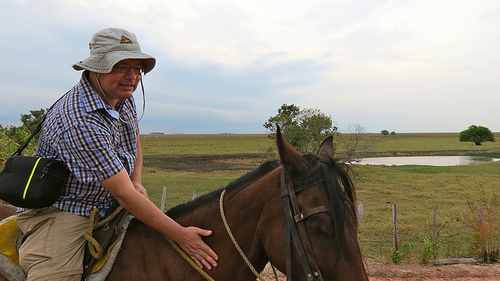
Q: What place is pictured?
A: It is a field.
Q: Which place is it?
A: It is a field.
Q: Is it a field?
A: Yes, it is a field.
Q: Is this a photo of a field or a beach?
A: It is showing a field.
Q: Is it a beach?
A: No, it is a field.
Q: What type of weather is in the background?
A: It is cloudy.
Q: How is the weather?
A: It is cloudy.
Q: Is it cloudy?
A: Yes, it is cloudy.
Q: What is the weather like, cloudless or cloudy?
A: It is cloudy.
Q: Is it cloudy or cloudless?
A: It is cloudy.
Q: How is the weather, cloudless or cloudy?
A: It is cloudy.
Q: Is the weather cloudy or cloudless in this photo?
A: It is cloudy.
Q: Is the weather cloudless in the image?
A: No, it is cloudy.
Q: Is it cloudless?
A: No, it is cloudy.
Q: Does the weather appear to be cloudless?
A: No, it is cloudy.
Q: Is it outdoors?
A: Yes, it is outdoors.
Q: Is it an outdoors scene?
A: Yes, it is outdoors.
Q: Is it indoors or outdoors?
A: It is outdoors.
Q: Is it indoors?
A: No, it is outdoors.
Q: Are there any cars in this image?
A: No, there are no cars.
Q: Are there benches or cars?
A: No, there are no cars or benches.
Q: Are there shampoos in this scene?
A: No, there are no shampoos.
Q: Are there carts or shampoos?
A: No, there are no shampoos or carts.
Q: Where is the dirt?
A: The dirt is in the field.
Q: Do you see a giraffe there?
A: No, there are no giraffes.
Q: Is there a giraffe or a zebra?
A: No, there are no giraffes or zebras.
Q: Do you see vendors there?
A: No, there are no vendors.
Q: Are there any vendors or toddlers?
A: No, there are no vendors or toddlers.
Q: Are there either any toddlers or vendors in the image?
A: No, there are no vendors or toddlers.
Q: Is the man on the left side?
A: Yes, the man is on the left of the image.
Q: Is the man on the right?
A: No, the man is on the left of the image.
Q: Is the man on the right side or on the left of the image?
A: The man is on the left of the image.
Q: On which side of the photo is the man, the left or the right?
A: The man is on the left of the image.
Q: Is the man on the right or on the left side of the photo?
A: The man is on the left of the image.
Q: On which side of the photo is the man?
A: The man is on the left of the image.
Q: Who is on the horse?
A: The man is on the horse.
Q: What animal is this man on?
A: The man is on the horse.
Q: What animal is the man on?
A: The man is on the horse.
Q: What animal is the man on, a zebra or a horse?
A: The man is on a horse.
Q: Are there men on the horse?
A: Yes, there is a man on the horse.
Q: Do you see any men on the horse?
A: Yes, there is a man on the horse.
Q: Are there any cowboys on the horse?
A: No, there is a man on the horse.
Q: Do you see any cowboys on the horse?
A: No, there is a man on the horse.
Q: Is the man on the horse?
A: Yes, the man is on the horse.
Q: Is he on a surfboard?
A: No, the man is on the horse.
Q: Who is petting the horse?
A: The man is petting the horse.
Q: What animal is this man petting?
A: The man is petting the horse.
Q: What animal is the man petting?
A: The man is petting the horse.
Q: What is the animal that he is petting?
A: The animal is a horse.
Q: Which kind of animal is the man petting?
A: The man is petting the horse.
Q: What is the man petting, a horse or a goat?
A: The man is petting a horse.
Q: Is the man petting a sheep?
A: No, the man is petting the horse.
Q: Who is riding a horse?
A: The man is riding a horse.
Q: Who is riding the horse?
A: The man is riding a horse.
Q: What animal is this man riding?
A: The man is riding a horse.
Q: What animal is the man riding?
A: The man is riding a horse.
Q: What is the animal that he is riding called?
A: The animal is a horse.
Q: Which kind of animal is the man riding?
A: The man is riding a horse.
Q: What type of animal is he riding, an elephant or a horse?
A: The man is riding a horse.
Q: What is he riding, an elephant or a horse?
A: The man is riding a horse.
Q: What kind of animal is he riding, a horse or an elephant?
A: The man is riding a horse.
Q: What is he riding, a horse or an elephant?
A: The man is riding a horse.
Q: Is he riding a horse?
A: Yes, the man is riding a horse.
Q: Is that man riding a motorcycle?
A: No, the man is riding a horse.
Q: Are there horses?
A: Yes, there is a horse.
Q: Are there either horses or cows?
A: Yes, there is a horse.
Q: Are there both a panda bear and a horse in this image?
A: No, there is a horse but no pandas.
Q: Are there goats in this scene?
A: No, there are no goats.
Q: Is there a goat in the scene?
A: No, there are no goats.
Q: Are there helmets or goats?
A: No, there are no goats or helmets.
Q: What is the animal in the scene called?
A: The animal is a horse.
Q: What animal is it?
A: The animal is a horse.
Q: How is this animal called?
A: This is a horse.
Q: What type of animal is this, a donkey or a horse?
A: This is a horse.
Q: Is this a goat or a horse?
A: This is a horse.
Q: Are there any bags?
A: Yes, there is a bag.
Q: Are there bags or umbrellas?
A: Yes, there is a bag.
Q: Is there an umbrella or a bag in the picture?
A: Yes, there is a bag.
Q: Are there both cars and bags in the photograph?
A: No, there is a bag but no cars.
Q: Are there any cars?
A: No, there are no cars.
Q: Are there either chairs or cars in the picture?
A: No, there are no cars or chairs.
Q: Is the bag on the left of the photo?
A: Yes, the bag is on the left of the image.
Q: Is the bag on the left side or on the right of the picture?
A: The bag is on the left of the image.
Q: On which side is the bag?
A: The bag is on the left of the image.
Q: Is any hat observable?
A: Yes, there is a hat.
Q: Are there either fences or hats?
A: Yes, there is a hat.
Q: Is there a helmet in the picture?
A: No, there are no helmets.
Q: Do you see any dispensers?
A: No, there are no dispensers.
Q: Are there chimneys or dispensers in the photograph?
A: No, there are no dispensers or chimneys.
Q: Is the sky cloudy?
A: Yes, the sky is cloudy.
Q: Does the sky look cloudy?
A: Yes, the sky is cloudy.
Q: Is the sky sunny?
A: No, the sky is cloudy.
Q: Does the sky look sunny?
A: No, the sky is cloudy.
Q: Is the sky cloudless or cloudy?
A: The sky is cloudy.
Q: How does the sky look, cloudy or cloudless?
A: The sky is cloudy.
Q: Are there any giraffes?
A: No, there are no giraffes.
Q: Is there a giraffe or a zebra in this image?
A: No, there are no giraffes or zebras.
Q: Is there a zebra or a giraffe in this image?
A: No, there are no giraffes or zebras.